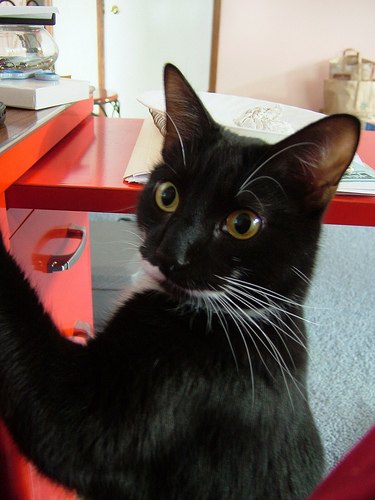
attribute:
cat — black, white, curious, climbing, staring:
[0, 64, 360, 499]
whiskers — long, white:
[185, 276, 340, 414]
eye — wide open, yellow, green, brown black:
[224, 209, 262, 241]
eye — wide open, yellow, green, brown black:
[152, 180, 179, 212]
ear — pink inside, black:
[288, 112, 361, 209]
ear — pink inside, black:
[163, 65, 214, 156]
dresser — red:
[0, 92, 94, 499]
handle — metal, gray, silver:
[51, 226, 88, 271]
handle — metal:
[74, 325, 90, 338]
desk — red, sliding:
[5, 115, 374, 230]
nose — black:
[159, 247, 186, 265]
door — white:
[99, 2, 218, 121]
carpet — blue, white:
[93, 214, 374, 485]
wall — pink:
[216, 3, 374, 124]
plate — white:
[0, 76, 89, 112]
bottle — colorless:
[0, 26, 58, 71]